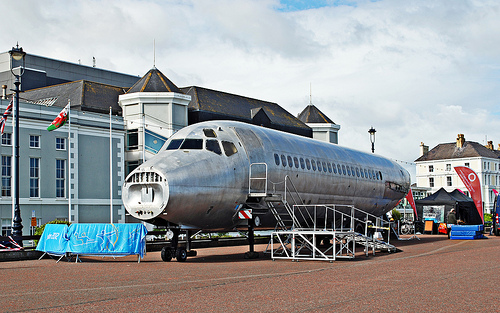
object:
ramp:
[253, 225, 395, 261]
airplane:
[120, 120, 410, 262]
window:
[273, 152, 280, 166]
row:
[273, 148, 386, 181]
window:
[280, 154, 289, 167]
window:
[287, 155, 293, 167]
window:
[292, 155, 300, 168]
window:
[300, 157, 305, 170]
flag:
[45, 99, 72, 132]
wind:
[43, 95, 77, 141]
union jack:
[0, 95, 17, 138]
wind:
[1, 88, 33, 154]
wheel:
[176, 247, 188, 262]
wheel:
[161, 246, 172, 262]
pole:
[108, 105, 113, 225]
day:
[1, 2, 499, 172]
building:
[412, 134, 500, 223]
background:
[282, 8, 499, 228]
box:
[450, 224, 483, 230]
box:
[449, 230, 481, 236]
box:
[449, 235, 476, 241]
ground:
[4, 231, 496, 313]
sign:
[35, 221, 148, 260]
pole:
[13, 73, 24, 244]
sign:
[453, 164, 483, 227]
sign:
[403, 187, 419, 220]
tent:
[415, 187, 484, 236]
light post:
[368, 126, 375, 153]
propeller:
[122, 168, 167, 221]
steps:
[246, 186, 301, 233]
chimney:
[485, 141, 495, 152]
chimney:
[455, 133, 465, 148]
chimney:
[419, 140, 428, 158]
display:
[115, 117, 415, 262]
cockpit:
[164, 136, 241, 156]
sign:
[237, 208, 253, 219]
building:
[0, 48, 340, 262]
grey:
[208, 92, 254, 112]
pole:
[66, 98, 72, 226]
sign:
[424, 220, 433, 231]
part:
[172, 177, 225, 202]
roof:
[413, 141, 500, 162]